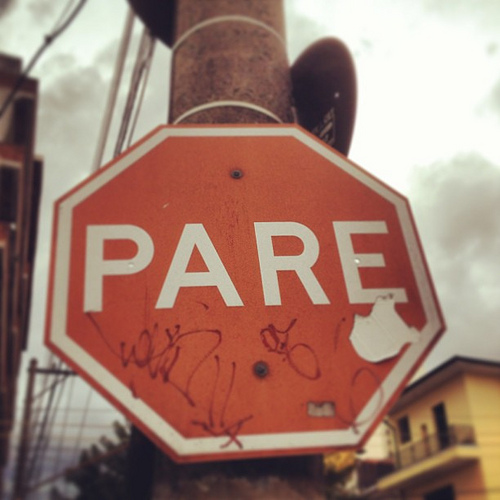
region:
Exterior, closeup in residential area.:
[12, 7, 494, 498]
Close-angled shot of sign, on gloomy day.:
[16, 18, 493, 498]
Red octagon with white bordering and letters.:
[58, 125, 438, 461]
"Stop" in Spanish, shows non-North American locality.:
[88, 219, 410, 325]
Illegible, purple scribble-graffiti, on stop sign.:
[113, 324, 347, 456]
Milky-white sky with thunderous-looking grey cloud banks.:
[432, 105, 496, 351]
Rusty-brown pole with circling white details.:
[171, 14, 296, 120]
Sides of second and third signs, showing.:
[131, 5, 357, 161]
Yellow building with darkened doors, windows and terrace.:
[373, 362, 498, 492]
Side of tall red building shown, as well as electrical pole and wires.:
[0, 5, 151, 497]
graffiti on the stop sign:
[112, 321, 258, 420]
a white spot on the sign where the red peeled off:
[337, 286, 419, 368]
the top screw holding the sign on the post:
[224, 156, 251, 186]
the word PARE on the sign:
[80, 214, 407, 334]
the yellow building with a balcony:
[362, 325, 484, 495]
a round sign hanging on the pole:
[285, 21, 366, 151]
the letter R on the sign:
[252, 208, 332, 315]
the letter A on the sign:
[155, 209, 262, 332]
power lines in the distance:
[22, 361, 94, 456]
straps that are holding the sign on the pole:
[178, 8, 286, 121]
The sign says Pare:
[61, 91, 492, 482]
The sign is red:
[60, 123, 460, 461]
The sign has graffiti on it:
[74, 131, 486, 486]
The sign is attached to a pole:
[60, 119, 477, 474]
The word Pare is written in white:
[45, 84, 447, 494]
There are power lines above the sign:
[33, 19, 462, 475]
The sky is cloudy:
[61, 112, 497, 494]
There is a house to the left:
[33, 77, 497, 456]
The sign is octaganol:
[37, 99, 473, 494]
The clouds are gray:
[30, 16, 497, 335]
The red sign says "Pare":
[23, 114, 499, 479]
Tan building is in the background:
[373, 337, 497, 499]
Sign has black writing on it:
[85, 285, 416, 455]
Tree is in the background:
[57, 412, 155, 497]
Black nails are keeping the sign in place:
[211, 145, 286, 405]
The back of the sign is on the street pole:
[259, 29, 403, 177]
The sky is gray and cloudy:
[1, 7, 498, 347]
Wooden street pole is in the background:
[8, 351, 82, 498]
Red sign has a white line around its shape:
[41, 121, 458, 480]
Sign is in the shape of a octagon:
[28, 90, 483, 467]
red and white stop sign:
[34, 93, 449, 433]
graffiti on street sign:
[103, 293, 407, 485]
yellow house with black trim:
[372, 322, 497, 484]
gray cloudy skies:
[395, 114, 499, 318]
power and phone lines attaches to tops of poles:
[13, 336, 120, 483]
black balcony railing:
[387, 406, 497, 476]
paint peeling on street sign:
[282, 203, 471, 449]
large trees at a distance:
[66, 398, 173, 499]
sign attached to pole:
[141, 13, 442, 195]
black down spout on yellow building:
[375, 415, 432, 481]